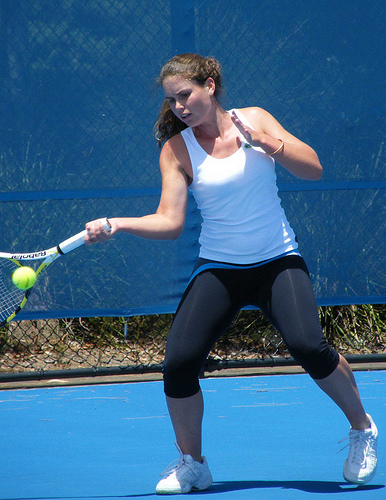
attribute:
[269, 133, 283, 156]
bracelet — thin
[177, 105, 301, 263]
shirt — white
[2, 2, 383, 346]
fence — chain link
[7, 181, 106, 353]
racket. — white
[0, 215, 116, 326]
racket — black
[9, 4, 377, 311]
object — blue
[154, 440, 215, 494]
shoe — white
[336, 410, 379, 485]
shoe — white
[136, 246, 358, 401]
pants — black